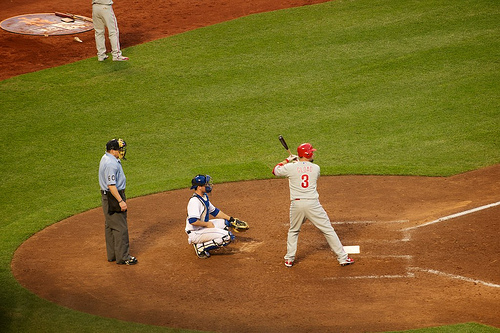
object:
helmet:
[190, 174, 208, 190]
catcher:
[183, 173, 250, 259]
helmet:
[296, 142, 319, 157]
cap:
[103, 136, 126, 148]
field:
[0, 0, 499, 332]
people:
[271, 142, 353, 268]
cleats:
[124, 259, 131, 266]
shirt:
[96, 151, 127, 191]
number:
[300, 175, 309, 189]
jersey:
[272, 161, 321, 202]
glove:
[228, 216, 250, 234]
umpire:
[97, 137, 137, 266]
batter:
[271, 143, 355, 268]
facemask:
[205, 175, 215, 194]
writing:
[295, 164, 315, 173]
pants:
[281, 200, 351, 263]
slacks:
[101, 189, 130, 261]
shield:
[115, 138, 128, 160]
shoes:
[282, 256, 294, 269]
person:
[90, 0, 130, 62]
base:
[342, 245, 361, 255]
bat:
[275, 134, 299, 162]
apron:
[107, 189, 128, 216]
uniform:
[183, 193, 236, 253]